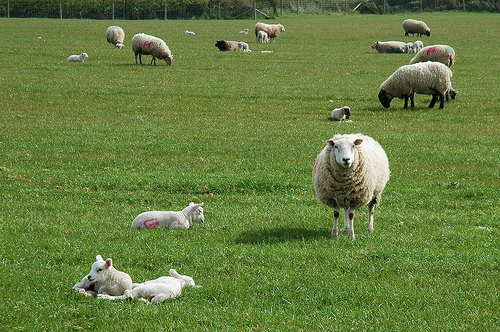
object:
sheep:
[311, 130, 392, 240]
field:
[2, 15, 499, 330]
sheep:
[377, 60, 455, 110]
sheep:
[407, 43, 456, 68]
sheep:
[401, 18, 432, 39]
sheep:
[131, 32, 173, 66]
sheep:
[105, 25, 127, 51]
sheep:
[254, 21, 286, 43]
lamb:
[131, 267, 203, 304]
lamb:
[72, 253, 132, 301]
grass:
[426, 34, 440, 41]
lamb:
[329, 105, 353, 122]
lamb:
[256, 29, 271, 44]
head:
[325, 137, 363, 169]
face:
[378, 89, 393, 109]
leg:
[403, 96, 410, 110]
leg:
[409, 92, 415, 108]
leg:
[427, 92, 437, 109]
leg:
[437, 92, 447, 110]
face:
[342, 107, 351, 117]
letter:
[425, 45, 436, 56]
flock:
[66, 52, 91, 63]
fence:
[2, 1, 497, 20]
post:
[162, 2, 170, 20]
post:
[252, 1, 259, 21]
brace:
[256, 6, 269, 19]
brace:
[236, 8, 253, 20]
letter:
[142, 39, 153, 49]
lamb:
[130, 201, 207, 230]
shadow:
[232, 225, 332, 246]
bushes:
[1, 0, 54, 20]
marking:
[144, 217, 160, 229]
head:
[87, 253, 114, 282]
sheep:
[370, 38, 408, 54]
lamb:
[405, 40, 413, 53]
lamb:
[410, 39, 424, 53]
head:
[114, 43, 126, 50]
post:
[57, 2, 65, 21]